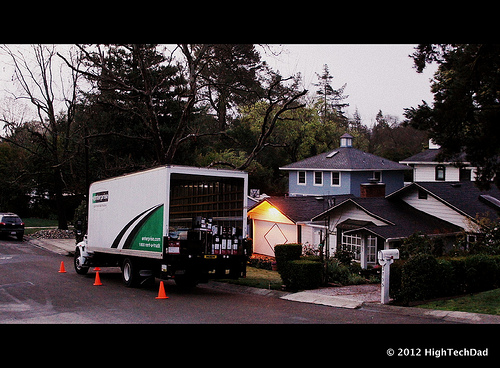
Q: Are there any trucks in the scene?
A: Yes, there is a truck.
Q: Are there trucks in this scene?
A: Yes, there is a truck.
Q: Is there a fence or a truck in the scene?
A: Yes, there is a truck.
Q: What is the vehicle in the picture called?
A: The vehicle is a truck.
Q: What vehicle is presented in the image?
A: The vehicle is a truck.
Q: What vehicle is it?
A: The vehicle is a truck.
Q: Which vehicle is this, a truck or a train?
A: This is a truck.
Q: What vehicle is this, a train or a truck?
A: This is a truck.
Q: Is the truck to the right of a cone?
A: Yes, the truck is to the right of a cone.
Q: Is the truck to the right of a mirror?
A: No, the truck is to the right of a cone.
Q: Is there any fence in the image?
A: No, there are no fences.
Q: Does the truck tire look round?
A: Yes, the tire is round.